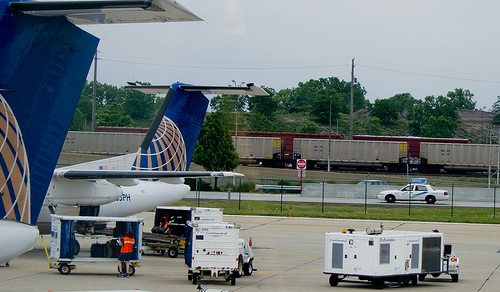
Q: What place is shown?
A: It is an airport.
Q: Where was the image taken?
A: It was taken at the airport.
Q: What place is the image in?
A: It is at the airport.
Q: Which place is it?
A: It is an airport.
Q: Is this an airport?
A: Yes, it is an airport.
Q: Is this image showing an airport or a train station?
A: It is showing an airport.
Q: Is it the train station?
A: No, it is the airport.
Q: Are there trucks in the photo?
A: Yes, there is a truck.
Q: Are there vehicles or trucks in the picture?
A: Yes, there is a truck.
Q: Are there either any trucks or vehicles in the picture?
A: Yes, there is a truck.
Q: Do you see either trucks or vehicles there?
A: Yes, there is a truck.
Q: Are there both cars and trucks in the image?
A: Yes, there are both a truck and a car.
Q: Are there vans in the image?
A: No, there are no vans.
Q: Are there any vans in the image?
A: No, there are no vans.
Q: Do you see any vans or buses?
A: No, there are no vans or buses.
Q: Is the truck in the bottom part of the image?
A: Yes, the truck is in the bottom of the image.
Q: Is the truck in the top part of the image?
A: No, the truck is in the bottom of the image.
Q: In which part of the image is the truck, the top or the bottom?
A: The truck is in the bottom of the image.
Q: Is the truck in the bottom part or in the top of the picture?
A: The truck is in the bottom of the image.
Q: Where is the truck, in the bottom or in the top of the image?
A: The truck is in the bottom of the image.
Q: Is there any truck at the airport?
A: Yes, there is a truck at the airport.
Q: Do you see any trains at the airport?
A: No, there is a truck at the airport.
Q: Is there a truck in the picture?
A: Yes, there is a truck.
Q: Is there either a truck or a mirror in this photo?
A: Yes, there is a truck.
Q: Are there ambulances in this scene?
A: No, there are no ambulances.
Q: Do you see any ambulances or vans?
A: No, there are no ambulances or vans.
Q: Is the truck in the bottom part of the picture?
A: Yes, the truck is in the bottom of the image.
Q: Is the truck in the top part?
A: No, the truck is in the bottom of the image.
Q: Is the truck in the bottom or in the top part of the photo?
A: The truck is in the bottom of the image.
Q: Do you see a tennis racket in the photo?
A: No, there are no rackets.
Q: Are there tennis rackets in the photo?
A: No, there are no tennis rackets.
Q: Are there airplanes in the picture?
A: Yes, there is an airplane.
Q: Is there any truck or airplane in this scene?
A: Yes, there is an airplane.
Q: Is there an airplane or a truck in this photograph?
A: Yes, there is an airplane.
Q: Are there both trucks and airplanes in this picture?
A: Yes, there are both an airplane and a truck.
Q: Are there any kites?
A: No, there are no kites.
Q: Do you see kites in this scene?
A: No, there are no kites.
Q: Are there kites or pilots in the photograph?
A: No, there are no kites or pilots.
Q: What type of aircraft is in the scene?
A: The aircraft is an airplane.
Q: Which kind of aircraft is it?
A: The aircraft is an airplane.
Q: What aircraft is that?
A: This is an airplane.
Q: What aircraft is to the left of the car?
A: The aircraft is an airplane.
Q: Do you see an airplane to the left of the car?
A: Yes, there is an airplane to the left of the car.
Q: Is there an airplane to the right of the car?
A: No, the airplane is to the left of the car.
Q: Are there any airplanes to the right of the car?
A: No, the airplane is to the left of the car.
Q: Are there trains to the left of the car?
A: No, there is an airplane to the left of the car.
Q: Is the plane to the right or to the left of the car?
A: The plane is to the left of the car.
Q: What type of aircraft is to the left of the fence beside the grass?
A: The aircraft is an airplane.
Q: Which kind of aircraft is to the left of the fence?
A: The aircraft is an airplane.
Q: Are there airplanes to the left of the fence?
A: Yes, there is an airplane to the left of the fence.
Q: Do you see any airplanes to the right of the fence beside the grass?
A: No, the airplane is to the left of the fence.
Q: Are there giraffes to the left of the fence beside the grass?
A: No, there is an airplane to the left of the fence.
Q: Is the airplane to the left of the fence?
A: Yes, the airplane is to the left of the fence.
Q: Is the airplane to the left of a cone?
A: No, the airplane is to the left of the fence.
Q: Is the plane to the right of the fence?
A: No, the plane is to the left of the fence.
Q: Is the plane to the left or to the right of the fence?
A: The plane is to the left of the fence.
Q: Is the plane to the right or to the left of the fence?
A: The plane is to the left of the fence.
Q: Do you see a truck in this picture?
A: Yes, there is a truck.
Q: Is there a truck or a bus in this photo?
A: Yes, there is a truck.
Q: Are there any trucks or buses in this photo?
A: Yes, there is a truck.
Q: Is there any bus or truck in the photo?
A: Yes, there is a truck.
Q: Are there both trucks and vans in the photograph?
A: No, there is a truck but no vans.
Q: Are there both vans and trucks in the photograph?
A: No, there is a truck but no vans.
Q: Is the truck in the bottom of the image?
A: Yes, the truck is in the bottom of the image.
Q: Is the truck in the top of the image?
A: No, the truck is in the bottom of the image.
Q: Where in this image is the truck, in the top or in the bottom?
A: The truck is in the bottom of the image.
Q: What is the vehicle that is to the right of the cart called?
A: The vehicle is a truck.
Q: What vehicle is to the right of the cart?
A: The vehicle is a truck.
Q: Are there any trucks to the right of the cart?
A: Yes, there is a truck to the right of the cart.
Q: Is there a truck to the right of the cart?
A: Yes, there is a truck to the right of the cart.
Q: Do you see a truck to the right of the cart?
A: Yes, there is a truck to the right of the cart.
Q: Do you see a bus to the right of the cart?
A: No, there is a truck to the right of the cart.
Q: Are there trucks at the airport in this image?
A: Yes, there is a truck at the airport.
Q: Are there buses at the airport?
A: No, there is a truck at the airport.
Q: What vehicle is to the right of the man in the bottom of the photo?
A: The vehicle is a truck.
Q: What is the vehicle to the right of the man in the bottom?
A: The vehicle is a truck.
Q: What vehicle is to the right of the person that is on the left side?
A: The vehicle is a truck.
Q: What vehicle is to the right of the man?
A: The vehicle is a truck.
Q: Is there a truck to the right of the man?
A: Yes, there is a truck to the right of the man.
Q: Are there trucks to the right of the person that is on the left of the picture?
A: Yes, there is a truck to the right of the man.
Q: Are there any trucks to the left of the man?
A: No, the truck is to the right of the man.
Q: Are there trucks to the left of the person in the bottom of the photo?
A: No, the truck is to the right of the man.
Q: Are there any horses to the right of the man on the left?
A: No, there is a truck to the right of the man.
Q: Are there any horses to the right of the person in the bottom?
A: No, there is a truck to the right of the man.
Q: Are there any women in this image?
A: No, there are no women.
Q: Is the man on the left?
A: Yes, the man is on the left of the image.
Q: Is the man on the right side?
A: No, the man is on the left of the image.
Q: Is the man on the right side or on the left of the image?
A: The man is on the left of the image.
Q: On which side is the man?
A: The man is on the left of the image.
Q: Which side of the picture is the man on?
A: The man is on the left of the image.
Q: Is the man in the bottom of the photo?
A: Yes, the man is in the bottom of the image.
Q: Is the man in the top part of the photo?
A: No, the man is in the bottom of the image.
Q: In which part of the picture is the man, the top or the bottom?
A: The man is in the bottom of the image.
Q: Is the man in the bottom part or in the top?
A: The man is in the bottom of the image.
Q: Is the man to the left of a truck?
A: Yes, the man is to the left of a truck.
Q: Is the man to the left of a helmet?
A: No, the man is to the left of a truck.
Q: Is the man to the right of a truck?
A: No, the man is to the left of a truck.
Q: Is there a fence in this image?
A: Yes, there is a fence.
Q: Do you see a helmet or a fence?
A: Yes, there is a fence.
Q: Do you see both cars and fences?
A: Yes, there are both a fence and a car.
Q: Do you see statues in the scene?
A: No, there are no statues.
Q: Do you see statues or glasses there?
A: No, there are no statues or glasses.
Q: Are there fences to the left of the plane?
A: No, the fence is to the right of the plane.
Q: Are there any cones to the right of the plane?
A: No, there is a fence to the right of the plane.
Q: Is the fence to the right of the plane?
A: Yes, the fence is to the right of the plane.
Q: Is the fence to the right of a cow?
A: No, the fence is to the right of the plane.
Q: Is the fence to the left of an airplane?
A: No, the fence is to the right of an airplane.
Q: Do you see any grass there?
A: Yes, there is grass.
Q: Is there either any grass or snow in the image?
A: Yes, there is grass.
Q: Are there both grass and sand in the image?
A: No, there is grass but no sand.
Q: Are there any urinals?
A: No, there are no urinals.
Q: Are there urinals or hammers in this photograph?
A: No, there are no urinals or hammers.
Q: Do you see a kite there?
A: No, there are no kites.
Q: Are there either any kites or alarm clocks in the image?
A: No, there are no kites or alarm clocks.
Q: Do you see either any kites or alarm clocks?
A: No, there are no kites or alarm clocks.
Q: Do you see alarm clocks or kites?
A: No, there are no kites or alarm clocks.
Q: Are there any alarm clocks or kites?
A: No, there are no kites or alarm clocks.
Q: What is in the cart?
A: The luggage is in the cart.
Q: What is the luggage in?
A: The luggage is in the cart.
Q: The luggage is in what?
A: The luggage is in the cart.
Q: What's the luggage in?
A: The luggage is in the cart.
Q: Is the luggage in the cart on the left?
A: Yes, the luggage is in the cart.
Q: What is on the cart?
A: The luggage is on the cart.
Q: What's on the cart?
A: The luggage is on the cart.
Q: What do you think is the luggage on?
A: The luggage is on the cart.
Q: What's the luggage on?
A: The luggage is on the cart.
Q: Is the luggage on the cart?
A: Yes, the luggage is on the cart.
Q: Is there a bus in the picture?
A: No, there are no buses.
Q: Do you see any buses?
A: No, there are no buses.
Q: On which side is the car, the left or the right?
A: The car is on the right of the image.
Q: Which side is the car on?
A: The car is on the right of the image.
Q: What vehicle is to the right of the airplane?
A: The vehicle is a car.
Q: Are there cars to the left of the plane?
A: No, the car is to the right of the plane.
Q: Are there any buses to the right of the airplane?
A: No, there is a car to the right of the airplane.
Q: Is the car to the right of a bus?
A: No, the car is to the right of the airplane.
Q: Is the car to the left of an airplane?
A: No, the car is to the right of an airplane.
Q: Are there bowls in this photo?
A: No, there are no bowls.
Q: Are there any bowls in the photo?
A: No, there are no bowls.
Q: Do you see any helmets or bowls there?
A: No, there are no bowls or helmets.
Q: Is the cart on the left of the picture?
A: Yes, the cart is on the left of the image.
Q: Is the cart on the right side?
A: No, the cart is on the left of the image.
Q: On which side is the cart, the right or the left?
A: The cart is on the left of the image.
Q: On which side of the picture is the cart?
A: The cart is on the left of the image.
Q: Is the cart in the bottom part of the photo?
A: Yes, the cart is in the bottom of the image.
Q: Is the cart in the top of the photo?
A: No, the cart is in the bottom of the image.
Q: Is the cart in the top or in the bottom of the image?
A: The cart is in the bottom of the image.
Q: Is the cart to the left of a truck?
A: Yes, the cart is to the left of a truck.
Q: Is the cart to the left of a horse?
A: No, the cart is to the left of a truck.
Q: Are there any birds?
A: No, there are no birds.